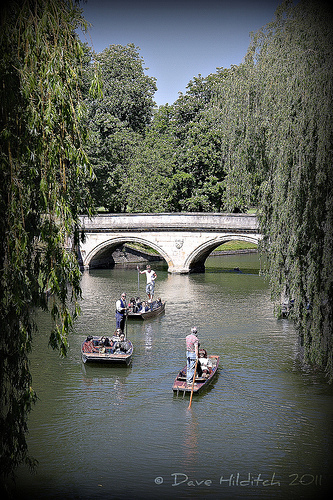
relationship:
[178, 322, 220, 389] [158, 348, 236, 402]
man in boat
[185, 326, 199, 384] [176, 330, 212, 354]
man in shirt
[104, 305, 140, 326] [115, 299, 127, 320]
shirt with vest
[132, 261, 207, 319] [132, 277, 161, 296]
man with shorts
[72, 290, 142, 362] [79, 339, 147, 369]
people with boat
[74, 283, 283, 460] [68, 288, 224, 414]
water with boats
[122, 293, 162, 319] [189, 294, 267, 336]
boat in water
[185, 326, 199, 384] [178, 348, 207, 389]
man in jeans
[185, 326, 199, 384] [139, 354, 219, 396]
man on boat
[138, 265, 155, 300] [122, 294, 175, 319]
man on boat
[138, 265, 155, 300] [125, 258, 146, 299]
man holding pole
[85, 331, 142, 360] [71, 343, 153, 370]
people on boat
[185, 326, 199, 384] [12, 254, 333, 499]
man on water